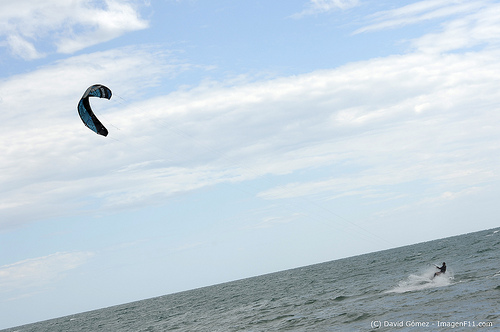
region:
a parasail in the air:
[65, 48, 217, 194]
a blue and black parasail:
[53, 53, 132, 146]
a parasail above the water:
[47, 58, 252, 322]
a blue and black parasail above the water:
[57, 41, 197, 178]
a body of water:
[319, 303, 389, 328]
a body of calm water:
[205, 264, 488, 329]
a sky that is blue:
[75, 26, 452, 242]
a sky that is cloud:
[98, 27, 440, 241]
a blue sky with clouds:
[62, 13, 497, 303]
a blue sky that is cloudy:
[74, 29, 469, 219]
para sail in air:
[61, 72, 122, 134]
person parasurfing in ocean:
[414, 246, 455, 286]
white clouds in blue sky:
[133, 37, 177, 81]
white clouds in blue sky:
[247, 151, 291, 177]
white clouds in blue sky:
[275, 18, 329, 81]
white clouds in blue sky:
[205, 217, 246, 248]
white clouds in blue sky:
[32, 241, 87, 272]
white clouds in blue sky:
[343, 51, 392, 99]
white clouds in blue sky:
[34, 46, 81, 68]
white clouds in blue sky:
[154, 190, 231, 229]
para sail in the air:
[48, 78, 128, 149]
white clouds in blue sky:
[17, 7, 65, 49]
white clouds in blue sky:
[14, 157, 67, 228]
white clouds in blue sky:
[85, 169, 126, 199]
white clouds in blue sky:
[232, 34, 296, 96]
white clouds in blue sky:
[348, 34, 403, 80]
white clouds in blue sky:
[169, 25, 242, 112]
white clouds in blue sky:
[226, 144, 302, 195]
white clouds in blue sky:
[137, 216, 219, 264]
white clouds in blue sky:
[292, 55, 400, 153]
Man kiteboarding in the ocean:
[73, 80, 448, 293]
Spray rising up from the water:
[381, 255, 456, 292]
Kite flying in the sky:
[75, 77, 110, 132]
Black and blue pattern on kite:
[75, 81, 107, 136]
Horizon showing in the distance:
[2, 227, 497, 329]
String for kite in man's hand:
[429, 251, 441, 271]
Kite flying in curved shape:
[76, 84, 112, 137]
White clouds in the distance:
[1, 6, 498, 226]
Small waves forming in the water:
[288, 294, 373, 328]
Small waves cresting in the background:
[484, 227, 499, 239]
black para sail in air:
[60, 70, 104, 152]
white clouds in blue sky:
[14, 21, 86, 78]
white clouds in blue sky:
[260, 46, 314, 88]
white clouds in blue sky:
[383, 71, 455, 141]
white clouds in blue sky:
[100, 241, 154, 268]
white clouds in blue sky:
[13, 181, 87, 225]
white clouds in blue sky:
[14, 83, 46, 130]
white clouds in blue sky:
[49, 230, 143, 281]